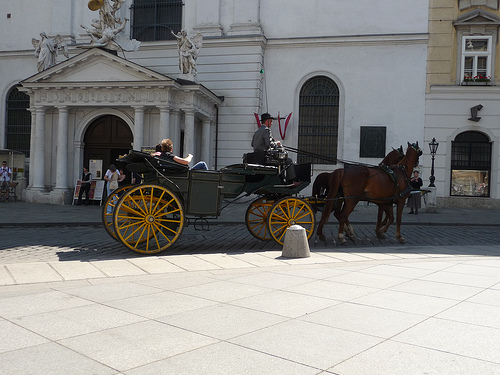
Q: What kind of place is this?
A: It is a street.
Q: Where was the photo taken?
A: It was taken at the street.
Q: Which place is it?
A: It is a street.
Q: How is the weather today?
A: It is sunny.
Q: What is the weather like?
A: It is sunny.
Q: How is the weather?
A: It is sunny.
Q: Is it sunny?
A: Yes, it is sunny.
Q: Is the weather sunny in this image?
A: Yes, it is sunny.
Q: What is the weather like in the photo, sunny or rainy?
A: It is sunny.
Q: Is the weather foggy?
A: No, it is sunny.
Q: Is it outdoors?
A: Yes, it is outdoors.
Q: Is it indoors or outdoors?
A: It is outdoors.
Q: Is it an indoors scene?
A: No, it is outdoors.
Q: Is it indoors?
A: No, it is outdoors.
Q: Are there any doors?
A: Yes, there is a door.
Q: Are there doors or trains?
A: Yes, there is a door.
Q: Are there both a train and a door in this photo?
A: No, there is a door but no trains.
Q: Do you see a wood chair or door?
A: Yes, there is a wood door.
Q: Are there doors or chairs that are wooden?
A: Yes, the door is wooden.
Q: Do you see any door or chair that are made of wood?
A: Yes, the door is made of wood.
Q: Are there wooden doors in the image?
A: Yes, there is a wood door.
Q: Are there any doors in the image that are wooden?
A: Yes, there is a door that is wooden.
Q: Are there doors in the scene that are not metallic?
A: Yes, there is a wooden door.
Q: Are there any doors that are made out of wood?
A: Yes, there is a door that is made of wood.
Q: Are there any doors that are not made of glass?
A: Yes, there is a door that is made of wood.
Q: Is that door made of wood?
A: Yes, the door is made of wood.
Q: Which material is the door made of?
A: The door is made of wood.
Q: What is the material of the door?
A: The door is made of wood.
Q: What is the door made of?
A: The door is made of wood.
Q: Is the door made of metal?
A: No, the door is made of wood.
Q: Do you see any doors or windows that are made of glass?
A: No, there is a door but it is made of wood.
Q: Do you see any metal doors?
A: No, there is a door but it is made of wood.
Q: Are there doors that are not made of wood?
A: No, there is a door but it is made of wood.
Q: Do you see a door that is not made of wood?
A: No, there is a door but it is made of wood.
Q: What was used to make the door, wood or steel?
A: The door is made of wood.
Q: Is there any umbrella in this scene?
A: No, there are no umbrellas.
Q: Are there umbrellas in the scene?
A: No, there are no umbrellas.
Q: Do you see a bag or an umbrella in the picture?
A: No, there are no umbrellas or bags.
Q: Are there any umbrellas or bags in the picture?
A: No, there are no umbrellas or bags.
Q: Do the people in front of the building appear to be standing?
A: Yes, the people are standing.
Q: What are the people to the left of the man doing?
A: The people are standing.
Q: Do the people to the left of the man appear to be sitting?
A: No, the people are standing.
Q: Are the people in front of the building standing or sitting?
A: The people are standing.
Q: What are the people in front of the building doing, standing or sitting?
A: The people are standing.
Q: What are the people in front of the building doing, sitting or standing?
A: The people are standing.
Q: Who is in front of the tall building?
A: The people are in front of the building.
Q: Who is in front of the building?
A: The people are in front of the building.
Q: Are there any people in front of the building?
A: Yes, there are people in front of the building.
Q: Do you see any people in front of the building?
A: Yes, there are people in front of the building.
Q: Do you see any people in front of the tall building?
A: Yes, there are people in front of the building.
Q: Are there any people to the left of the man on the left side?
A: Yes, there are people to the left of the man.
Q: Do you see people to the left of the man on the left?
A: Yes, there are people to the left of the man.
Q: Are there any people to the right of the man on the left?
A: No, the people are to the left of the man.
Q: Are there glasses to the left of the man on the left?
A: No, there are people to the left of the man.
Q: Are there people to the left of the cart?
A: Yes, there are people to the left of the cart.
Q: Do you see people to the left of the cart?
A: Yes, there are people to the left of the cart.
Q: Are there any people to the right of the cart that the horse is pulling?
A: No, the people are to the left of the cart.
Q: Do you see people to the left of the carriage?
A: Yes, there are people to the left of the carriage.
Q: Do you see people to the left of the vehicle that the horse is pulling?
A: Yes, there are people to the left of the carriage.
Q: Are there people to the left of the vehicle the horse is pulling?
A: Yes, there are people to the left of the carriage.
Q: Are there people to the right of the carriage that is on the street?
A: No, the people are to the left of the carriage.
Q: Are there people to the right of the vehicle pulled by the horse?
A: No, the people are to the left of the carriage.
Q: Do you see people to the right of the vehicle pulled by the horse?
A: No, the people are to the left of the carriage.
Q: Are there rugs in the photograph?
A: No, there are no rugs.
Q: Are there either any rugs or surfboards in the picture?
A: No, there are no rugs or surfboards.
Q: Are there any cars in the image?
A: No, there are no cars.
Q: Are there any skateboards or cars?
A: No, there are no cars or skateboards.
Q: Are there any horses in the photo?
A: Yes, there is a horse.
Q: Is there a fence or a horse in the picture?
A: Yes, there is a horse.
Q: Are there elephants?
A: No, there are no elephants.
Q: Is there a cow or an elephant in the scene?
A: No, there are no elephants or cows.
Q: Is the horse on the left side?
A: No, the horse is on the right of the image.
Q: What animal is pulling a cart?
A: The horse is pulling a cart.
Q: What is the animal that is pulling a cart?
A: The animal is a horse.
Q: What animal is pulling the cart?
A: The animal is a horse.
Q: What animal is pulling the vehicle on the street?
A: The horse is pulling the carriage.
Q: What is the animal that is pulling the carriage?
A: The animal is a horse.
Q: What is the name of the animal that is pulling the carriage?
A: The animal is a horse.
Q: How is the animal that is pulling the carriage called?
A: The animal is a horse.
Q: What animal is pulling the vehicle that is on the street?
A: The animal is a horse.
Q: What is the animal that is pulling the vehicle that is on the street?
A: The animal is a horse.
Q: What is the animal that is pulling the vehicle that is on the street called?
A: The animal is a horse.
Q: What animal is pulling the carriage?
A: The animal is a horse.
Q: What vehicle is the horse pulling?
A: The horse is pulling the carriage.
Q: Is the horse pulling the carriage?
A: Yes, the horse is pulling the carriage.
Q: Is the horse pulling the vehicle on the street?
A: Yes, the horse is pulling the carriage.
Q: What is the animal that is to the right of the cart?
A: The animal is a horse.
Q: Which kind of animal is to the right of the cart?
A: The animal is a horse.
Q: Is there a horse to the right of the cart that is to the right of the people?
A: Yes, there is a horse to the right of the cart.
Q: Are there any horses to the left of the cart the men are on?
A: No, the horse is to the right of the cart.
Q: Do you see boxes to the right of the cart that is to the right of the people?
A: No, there is a horse to the right of the cart.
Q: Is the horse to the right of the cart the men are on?
A: Yes, the horse is to the right of the cart.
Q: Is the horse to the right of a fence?
A: No, the horse is to the right of the cart.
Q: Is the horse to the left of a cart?
A: No, the horse is to the right of a cart.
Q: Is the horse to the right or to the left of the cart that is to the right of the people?
A: The horse is to the right of the cart.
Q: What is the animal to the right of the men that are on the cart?
A: The animal is a horse.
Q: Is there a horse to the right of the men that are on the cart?
A: Yes, there is a horse to the right of the men.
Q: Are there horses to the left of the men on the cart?
A: No, the horse is to the right of the men.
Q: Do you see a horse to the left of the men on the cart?
A: No, the horse is to the right of the men.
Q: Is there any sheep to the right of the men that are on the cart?
A: No, there is a horse to the right of the men.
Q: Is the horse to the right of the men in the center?
A: Yes, the horse is to the right of the men.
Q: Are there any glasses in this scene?
A: No, there are no glasses.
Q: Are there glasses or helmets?
A: No, there are no glasses or helmets.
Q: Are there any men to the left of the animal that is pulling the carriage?
A: Yes, there are men to the left of the horse.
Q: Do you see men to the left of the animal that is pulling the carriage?
A: Yes, there are men to the left of the horse.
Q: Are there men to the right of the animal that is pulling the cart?
A: No, the men are to the left of the horse.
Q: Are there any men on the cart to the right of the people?
A: Yes, there are men on the cart.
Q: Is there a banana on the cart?
A: No, there are men on the cart.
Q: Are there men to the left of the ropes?
A: Yes, there are men to the left of the ropes.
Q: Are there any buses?
A: No, there are no buses.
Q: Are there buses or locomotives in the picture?
A: No, there are no buses or locomotives.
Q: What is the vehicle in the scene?
A: The vehicle is a carriage.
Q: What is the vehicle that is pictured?
A: The vehicle is a carriage.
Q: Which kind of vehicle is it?
A: The vehicle is a carriage.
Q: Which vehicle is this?
A: This is a carriage.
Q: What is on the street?
A: The carriage is on the street.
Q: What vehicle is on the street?
A: The vehicle is a carriage.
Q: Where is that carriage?
A: The carriage is on the street.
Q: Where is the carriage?
A: The carriage is on the street.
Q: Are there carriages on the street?
A: Yes, there is a carriage on the street.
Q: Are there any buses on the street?
A: No, there is a carriage on the street.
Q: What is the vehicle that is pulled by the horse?
A: The vehicle is a carriage.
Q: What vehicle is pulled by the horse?
A: The vehicle is a carriage.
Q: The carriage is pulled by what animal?
A: The carriage is pulled by the horse.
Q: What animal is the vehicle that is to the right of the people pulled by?
A: The carriage is pulled by the horse.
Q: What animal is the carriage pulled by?
A: The carriage is pulled by the horse.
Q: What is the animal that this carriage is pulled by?
A: The animal is a horse.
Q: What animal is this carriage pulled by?
A: The carriage is pulled by the horse.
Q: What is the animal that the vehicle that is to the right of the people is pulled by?
A: The animal is a horse.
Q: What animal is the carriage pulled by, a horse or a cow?
A: The carriage is pulled by a horse.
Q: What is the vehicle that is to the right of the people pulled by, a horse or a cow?
A: The carriage is pulled by a horse.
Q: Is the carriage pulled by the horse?
A: Yes, the carriage is pulled by the horse.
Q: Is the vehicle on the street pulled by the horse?
A: Yes, the carriage is pulled by the horse.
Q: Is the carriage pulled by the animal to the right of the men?
A: Yes, the carriage is pulled by the horse.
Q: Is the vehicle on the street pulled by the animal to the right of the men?
A: Yes, the carriage is pulled by the horse.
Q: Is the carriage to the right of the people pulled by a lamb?
A: No, the carriage is pulled by the horse.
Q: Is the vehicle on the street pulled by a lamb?
A: No, the carriage is pulled by the horse.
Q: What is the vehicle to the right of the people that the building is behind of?
A: The vehicle is a carriage.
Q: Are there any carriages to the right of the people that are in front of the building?
A: Yes, there is a carriage to the right of the people.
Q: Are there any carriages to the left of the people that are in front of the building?
A: No, the carriage is to the right of the people.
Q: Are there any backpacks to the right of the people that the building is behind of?
A: No, there is a carriage to the right of the people.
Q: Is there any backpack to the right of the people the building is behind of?
A: No, there is a carriage to the right of the people.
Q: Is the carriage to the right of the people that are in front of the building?
A: Yes, the carriage is to the right of the people.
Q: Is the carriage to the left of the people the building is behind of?
A: No, the carriage is to the right of the people.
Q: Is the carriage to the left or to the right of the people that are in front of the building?
A: The carriage is to the right of the people.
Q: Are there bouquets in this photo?
A: No, there are no bouquets.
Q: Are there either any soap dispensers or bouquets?
A: No, there are no bouquets or soap dispensers.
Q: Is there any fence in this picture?
A: No, there are no fences.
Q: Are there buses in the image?
A: No, there are no buses.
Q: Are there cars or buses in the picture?
A: No, there are no buses or cars.